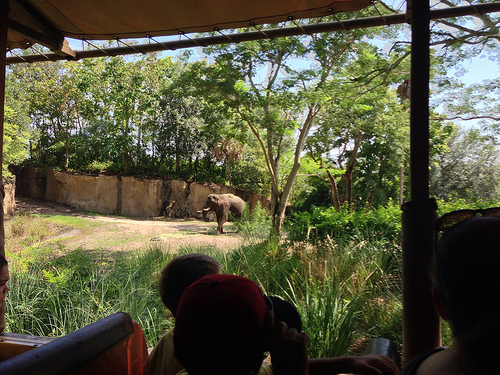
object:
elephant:
[198, 192, 251, 235]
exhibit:
[11, 28, 409, 333]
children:
[154, 247, 312, 375]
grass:
[12, 243, 401, 327]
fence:
[1, 334, 44, 360]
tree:
[201, 37, 373, 252]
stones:
[118, 176, 165, 218]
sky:
[429, 20, 500, 200]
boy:
[172, 274, 317, 373]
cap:
[180, 275, 300, 352]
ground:
[13, 196, 357, 266]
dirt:
[15, 206, 200, 248]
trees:
[106, 46, 148, 177]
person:
[405, 208, 499, 375]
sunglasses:
[433, 207, 499, 245]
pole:
[400, 3, 441, 374]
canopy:
[6, 2, 498, 66]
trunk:
[200, 200, 210, 223]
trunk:
[267, 184, 287, 244]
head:
[207, 195, 217, 213]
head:
[431, 212, 500, 323]